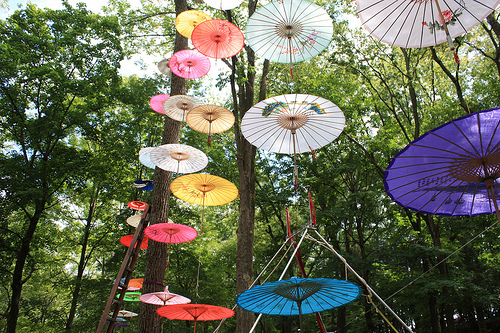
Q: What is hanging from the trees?
A: Umbrellas.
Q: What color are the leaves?
A: Green.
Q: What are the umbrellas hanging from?
A: Trees.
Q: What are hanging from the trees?
A: Umbrellas.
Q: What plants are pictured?
A: Trees.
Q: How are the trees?
A: Very tall.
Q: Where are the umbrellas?
A: In the forest.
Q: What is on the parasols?
A: Patterns.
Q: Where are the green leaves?
A: On the trees.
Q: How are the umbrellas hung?
A: With string.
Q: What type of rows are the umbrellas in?
A: Vertical rows.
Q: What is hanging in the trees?
A: Umbrellas.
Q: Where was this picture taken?
A: A forest.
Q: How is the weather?
A: Sunny.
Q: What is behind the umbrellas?
A: Trees.